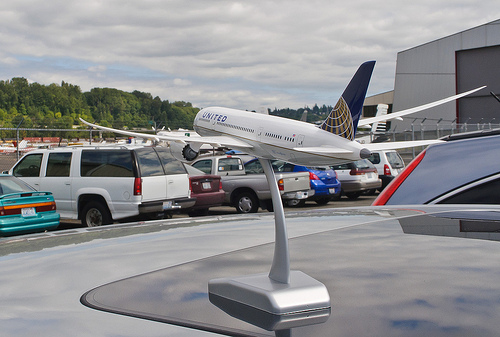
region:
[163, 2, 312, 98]
this is the sky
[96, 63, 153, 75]
the sky is blue in color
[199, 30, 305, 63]
this is the clouds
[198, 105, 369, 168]
this is a jet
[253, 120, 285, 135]
the jet is white in color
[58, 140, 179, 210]
this is a vehicle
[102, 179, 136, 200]
the vehicle is white in color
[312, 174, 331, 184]
the car is blue in color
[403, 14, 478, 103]
this is a building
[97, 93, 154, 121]
this is a forest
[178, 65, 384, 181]
the plane is owned by united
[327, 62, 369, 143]
the tail is blue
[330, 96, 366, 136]
world image is on the tail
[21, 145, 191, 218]
the truck is white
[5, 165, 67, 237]
the car is green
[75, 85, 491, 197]
the plane is on the car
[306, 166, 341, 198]
the car is blue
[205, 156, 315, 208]
the pickup is ilver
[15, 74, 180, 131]
trees are in the background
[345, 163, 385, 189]
the van is white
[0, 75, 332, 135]
the trees in the distance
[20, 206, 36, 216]
the license plate on the car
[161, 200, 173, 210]
the license plate on the car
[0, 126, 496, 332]
the parked cars in the lot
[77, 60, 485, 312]
the model airplane on a car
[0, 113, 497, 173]
the chain link fence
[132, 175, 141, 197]
the light on the SUV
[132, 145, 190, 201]
the two doors on the back of the SUV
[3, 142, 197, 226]
the large and white SUV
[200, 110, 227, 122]
the word UNITED on the model airplane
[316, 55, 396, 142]
tail of the plane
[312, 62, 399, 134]
blue tail of plane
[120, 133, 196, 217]
back of the car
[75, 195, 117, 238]
tire on the car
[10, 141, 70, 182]
side windows of car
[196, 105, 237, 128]
word on side of plane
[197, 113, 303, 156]
windows on side of plane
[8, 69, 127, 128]
trees in the distance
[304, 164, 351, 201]
back of the blue car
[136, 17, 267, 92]
clouds in the sky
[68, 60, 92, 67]
this is the sky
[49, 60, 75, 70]
the sky is blue in color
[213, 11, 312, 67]
the sky has clouds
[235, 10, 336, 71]
the clouds are white in color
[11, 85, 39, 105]
this is a tree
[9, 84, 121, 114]
the leaves are green in color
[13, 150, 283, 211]
these are some cars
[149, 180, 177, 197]
the car is white in color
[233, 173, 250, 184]
the car is grey in color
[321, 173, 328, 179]
the car is blue in color